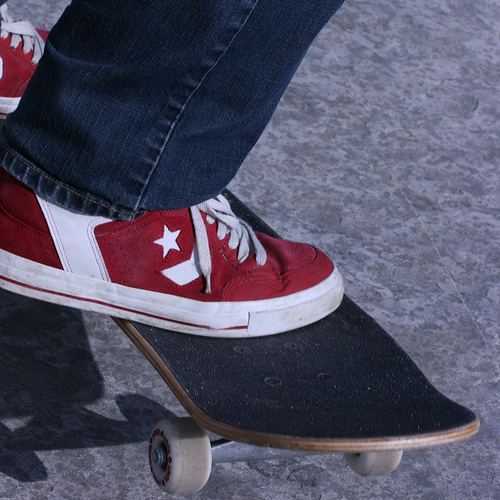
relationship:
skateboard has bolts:
[89, 170, 476, 483] [234, 337, 339, 391]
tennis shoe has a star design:
[2, 166, 344, 340] [152, 223, 187, 259]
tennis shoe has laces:
[2, 166, 344, 340] [193, 187, 268, 301]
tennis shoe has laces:
[1, 1, 60, 116] [3, 3, 51, 67]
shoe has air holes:
[2, 166, 344, 340] [109, 239, 136, 286]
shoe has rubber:
[2, 166, 344, 340] [3, 247, 342, 341]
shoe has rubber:
[1, 1, 60, 116] [3, 94, 29, 121]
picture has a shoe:
[2, 1, 499, 498] [2, 166, 344, 340]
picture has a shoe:
[2, 1, 499, 498] [1, 1, 60, 116]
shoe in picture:
[2, 166, 344, 340] [2, 1, 499, 498]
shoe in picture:
[1, 1, 60, 116] [2, 1, 499, 498]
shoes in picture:
[3, 14, 346, 338] [2, 1, 499, 498]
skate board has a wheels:
[89, 170, 476, 483] [148, 415, 213, 493]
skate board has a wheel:
[89, 170, 476, 483] [349, 436, 410, 478]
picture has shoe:
[2, 1, 499, 498] [2, 166, 344, 340]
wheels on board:
[148, 420, 405, 495] [89, 170, 476, 483]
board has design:
[89, 170, 476, 483] [146, 425, 173, 489]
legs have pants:
[2, 0, 349, 218] [3, 14, 346, 338]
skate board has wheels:
[89, 170, 476, 483] [148, 415, 213, 493]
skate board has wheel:
[89, 170, 476, 483] [349, 436, 410, 478]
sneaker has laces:
[2, 166, 344, 340] [193, 187, 268, 301]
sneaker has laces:
[1, 1, 60, 116] [3, 3, 51, 67]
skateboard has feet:
[89, 170, 476, 483] [3, 14, 346, 338]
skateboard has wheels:
[89, 170, 476, 483] [148, 420, 405, 495]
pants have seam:
[3, 14, 346, 338] [118, 0, 266, 222]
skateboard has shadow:
[89, 170, 476, 483] [0, 291, 191, 481]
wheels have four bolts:
[148, 420, 405, 495] [234, 337, 339, 391]